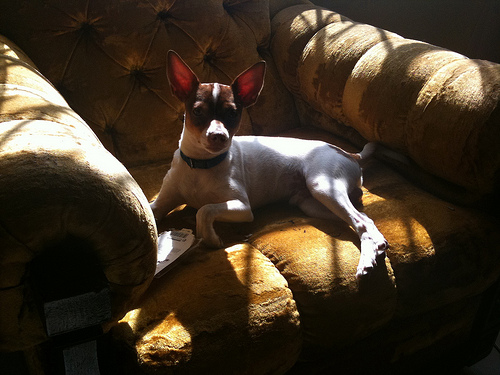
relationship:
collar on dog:
[175, 149, 228, 171] [148, 50, 403, 280]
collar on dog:
[175, 146, 233, 171] [148, 42, 388, 286]